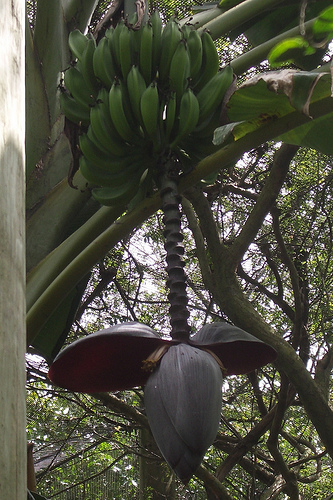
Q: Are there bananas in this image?
A: Yes, there is a banana.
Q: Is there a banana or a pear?
A: Yes, there is a banana.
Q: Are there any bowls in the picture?
A: No, there are no bowls.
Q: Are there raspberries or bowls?
A: No, there are no bowls or raspberries.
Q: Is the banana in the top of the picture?
A: Yes, the banana is in the top of the image.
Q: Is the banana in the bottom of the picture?
A: No, the banana is in the top of the image.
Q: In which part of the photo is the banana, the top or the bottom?
A: The banana is in the top of the image.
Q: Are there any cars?
A: No, there are no cars.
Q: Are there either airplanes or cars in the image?
A: No, there are no cars or airplanes.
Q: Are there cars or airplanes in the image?
A: No, there are no cars or airplanes.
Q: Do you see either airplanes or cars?
A: No, there are no cars or airplanes.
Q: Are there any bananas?
A: Yes, there is a banana.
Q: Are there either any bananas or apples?
A: Yes, there is a banana.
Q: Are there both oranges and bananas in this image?
A: No, there is a banana but no oranges.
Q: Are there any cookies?
A: No, there are no cookies.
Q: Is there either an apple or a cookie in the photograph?
A: No, there are no cookies or apples.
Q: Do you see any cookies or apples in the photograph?
A: No, there are no cookies or apples.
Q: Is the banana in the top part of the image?
A: Yes, the banana is in the top of the image.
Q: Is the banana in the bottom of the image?
A: No, the banana is in the top of the image.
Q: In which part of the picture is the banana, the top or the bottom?
A: The banana is in the top of the image.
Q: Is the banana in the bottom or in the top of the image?
A: The banana is in the top of the image.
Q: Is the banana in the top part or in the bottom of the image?
A: The banana is in the top of the image.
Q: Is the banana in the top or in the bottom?
A: The banana is in the top of the image.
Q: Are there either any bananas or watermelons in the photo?
A: Yes, there is a banana.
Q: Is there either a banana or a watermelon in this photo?
A: Yes, there is a banana.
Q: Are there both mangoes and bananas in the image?
A: No, there is a banana but no mangoes.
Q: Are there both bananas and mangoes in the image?
A: No, there is a banana but no mangoes.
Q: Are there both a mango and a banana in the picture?
A: No, there is a banana but no mangoes.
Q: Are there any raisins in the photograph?
A: No, there are no raisins.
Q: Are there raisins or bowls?
A: No, there are no raisins or bowls.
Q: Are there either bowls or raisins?
A: No, there are no raisins or bowls.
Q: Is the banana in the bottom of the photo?
A: No, the banana is in the top of the image.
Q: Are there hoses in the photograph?
A: No, there are no hoses.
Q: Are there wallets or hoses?
A: No, there are no hoses or wallets.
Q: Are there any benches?
A: No, there are no benches.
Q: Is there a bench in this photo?
A: No, there are no benches.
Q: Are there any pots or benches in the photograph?
A: No, there are no benches or pots.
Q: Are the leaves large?
A: Yes, the leaves are large.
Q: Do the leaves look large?
A: Yes, the leaves are large.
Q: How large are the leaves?
A: The leaves are large.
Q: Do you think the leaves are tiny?
A: No, the leaves are large.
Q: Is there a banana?
A: Yes, there are bananas.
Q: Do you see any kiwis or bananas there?
A: Yes, there are bananas.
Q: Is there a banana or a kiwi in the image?
A: Yes, there are bananas.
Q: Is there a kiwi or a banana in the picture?
A: Yes, there are bananas.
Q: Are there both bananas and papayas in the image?
A: No, there are bananas but no papayas.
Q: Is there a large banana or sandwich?
A: Yes, there are large bananas.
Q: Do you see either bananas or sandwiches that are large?
A: Yes, the bananas are large.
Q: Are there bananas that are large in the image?
A: Yes, there are large bananas.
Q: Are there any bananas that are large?
A: Yes, there are bananas that are large.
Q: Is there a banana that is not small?
A: Yes, there are large bananas.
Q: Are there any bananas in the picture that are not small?
A: Yes, there are large bananas.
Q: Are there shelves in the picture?
A: No, there are no shelves.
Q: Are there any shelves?
A: No, there are no shelves.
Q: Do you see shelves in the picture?
A: No, there are no shelves.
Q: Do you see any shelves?
A: No, there are no shelves.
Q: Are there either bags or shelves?
A: No, there are no shelves or bags.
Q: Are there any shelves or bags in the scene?
A: No, there are no shelves or bags.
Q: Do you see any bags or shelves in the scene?
A: No, there are no shelves or bags.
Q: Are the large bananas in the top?
A: Yes, the bananas are in the top of the image.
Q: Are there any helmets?
A: No, there are no helmets.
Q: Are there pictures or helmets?
A: No, there are no helmets or pictures.